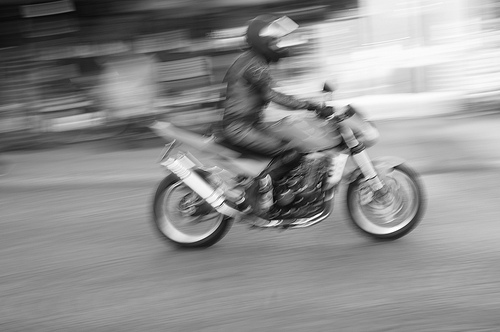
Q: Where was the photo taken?
A: It was taken at the road.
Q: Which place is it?
A: It is a road.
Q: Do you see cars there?
A: No, there are no cars.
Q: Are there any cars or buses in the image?
A: No, there are no cars or buses.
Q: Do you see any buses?
A: No, there are no buses.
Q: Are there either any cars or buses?
A: No, there are no buses or cars.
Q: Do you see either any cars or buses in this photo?
A: No, there are no buses or cars.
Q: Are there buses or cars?
A: No, there are no buses or cars.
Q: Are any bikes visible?
A: Yes, there is a bike.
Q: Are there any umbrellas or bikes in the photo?
A: Yes, there is a bike.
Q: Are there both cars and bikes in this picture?
A: No, there is a bike but no cars.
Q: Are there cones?
A: No, there are no cones.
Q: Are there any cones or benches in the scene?
A: No, there are no cones or benches.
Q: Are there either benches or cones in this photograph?
A: No, there are no cones or benches.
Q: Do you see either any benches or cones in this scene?
A: No, there are no cones or benches.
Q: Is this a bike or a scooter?
A: This is a bike.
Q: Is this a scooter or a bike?
A: This is a bike.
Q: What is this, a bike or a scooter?
A: This is a bike.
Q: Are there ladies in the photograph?
A: No, there are no ladies.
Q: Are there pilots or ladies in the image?
A: No, there are no ladies or pilots.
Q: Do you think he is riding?
A: Yes, the man is riding.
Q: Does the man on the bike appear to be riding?
A: Yes, the man is riding.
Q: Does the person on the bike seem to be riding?
A: Yes, the man is riding.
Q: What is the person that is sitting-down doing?
A: The man is riding.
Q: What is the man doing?
A: The man is riding.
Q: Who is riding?
A: The man is riding.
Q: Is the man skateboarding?
A: No, the man is riding.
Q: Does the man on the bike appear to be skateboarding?
A: No, the man is riding.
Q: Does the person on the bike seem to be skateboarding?
A: No, the man is riding.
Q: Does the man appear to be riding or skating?
A: The man is riding.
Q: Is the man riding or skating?
A: The man is riding.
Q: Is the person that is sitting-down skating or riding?
A: The man is riding.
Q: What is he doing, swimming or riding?
A: The man is riding.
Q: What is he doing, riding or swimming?
A: The man is riding.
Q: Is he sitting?
A: Yes, the man is sitting.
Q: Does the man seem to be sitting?
A: Yes, the man is sitting.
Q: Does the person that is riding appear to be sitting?
A: Yes, the man is sitting.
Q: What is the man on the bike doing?
A: The man is sitting.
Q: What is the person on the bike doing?
A: The man is sitting.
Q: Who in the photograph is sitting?
A: The man is sitting.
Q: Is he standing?
A: No, the man is sitting.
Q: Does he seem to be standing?
A: No, the man is sitting.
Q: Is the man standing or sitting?
A: The man is sitting.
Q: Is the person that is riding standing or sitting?
A: The man is sitting.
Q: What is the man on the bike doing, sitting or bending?
A: The man is sitting.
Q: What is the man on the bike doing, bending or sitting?
A: The man is sitting.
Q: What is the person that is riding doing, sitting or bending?
A: The man is sitting.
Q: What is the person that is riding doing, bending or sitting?
A: The man is sitting.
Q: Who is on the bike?
A: The man is on the bike.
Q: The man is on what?
A: The man is on the bike.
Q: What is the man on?
A: The man is on the bike.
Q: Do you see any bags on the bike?
A: No, there is a man on the bike.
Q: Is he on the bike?
A: Yes, the man is on the bike.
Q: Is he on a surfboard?
A: No, the man is on the bike.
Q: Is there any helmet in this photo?
A: Yes, there is a helmet.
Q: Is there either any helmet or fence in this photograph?
A: Yes, there is a helmet.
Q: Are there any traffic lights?
A: No, there are no traffic lights.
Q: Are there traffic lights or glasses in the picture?
A: No, there are no traffic lights or glasses.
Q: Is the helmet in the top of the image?
A: Yes, the helmet is in the top of the image.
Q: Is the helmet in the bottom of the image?
A: No, the helmet is in the top of the image.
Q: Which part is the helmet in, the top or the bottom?
A: The helmet is in the top of the image.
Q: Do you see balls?
A: No, there are no balls.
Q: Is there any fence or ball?
A: No, there are no balls or fences.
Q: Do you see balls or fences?
A: No, there are no balls or fences.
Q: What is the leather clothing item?
A: The clothing item is an outfit.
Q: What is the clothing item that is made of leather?
A: The clothing item is an outfit.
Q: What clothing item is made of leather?
A: The clothing item is an outfit.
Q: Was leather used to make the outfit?
A: Yes, the outfit is made of leather.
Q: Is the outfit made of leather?
A: Yes, the outfit is made of leather.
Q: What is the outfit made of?
A: The outfit is made of leather.